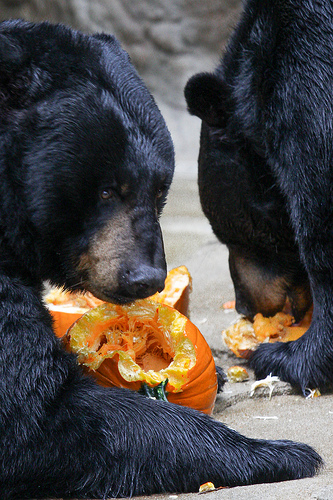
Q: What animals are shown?
A: Black and brown bears.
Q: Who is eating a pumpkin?
A: The bears.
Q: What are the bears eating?
A: Pumpkins.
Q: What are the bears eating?
A: Pumpkins.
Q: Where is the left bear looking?
A: To the right.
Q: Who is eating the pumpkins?
A: Two bears.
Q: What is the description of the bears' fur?
A: The fur is black.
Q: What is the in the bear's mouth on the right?
A: Pumpkin.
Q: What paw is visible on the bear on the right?
A: The right paw.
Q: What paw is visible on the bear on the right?
A: The left paw.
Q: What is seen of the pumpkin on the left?
A: The interior of the pumpkin.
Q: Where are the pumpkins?
A: Below the faces of the bears.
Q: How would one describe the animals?
A: Black bears.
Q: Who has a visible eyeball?
A: Bear on left.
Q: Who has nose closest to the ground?
A: Bear on right.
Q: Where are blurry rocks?
A: Top center of the scene.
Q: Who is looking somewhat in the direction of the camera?
A: Bear on left.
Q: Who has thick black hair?
A: Both bears.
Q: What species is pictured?
A: Bears.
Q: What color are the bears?
A: Black.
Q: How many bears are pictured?
A: Two.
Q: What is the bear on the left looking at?
A: The camera.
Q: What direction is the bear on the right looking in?
A: Down.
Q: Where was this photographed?
A: Zoo.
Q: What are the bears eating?
A: Pumpkin.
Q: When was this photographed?
A: Daytime.